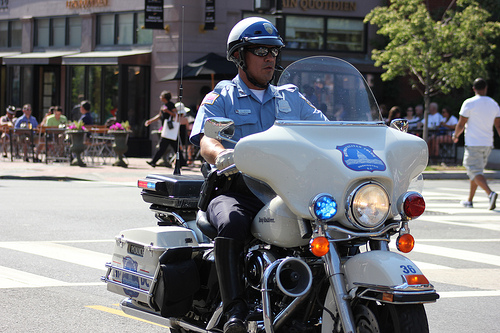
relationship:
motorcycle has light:
[92, 46, 432, 330] [347, 181, 393, 228]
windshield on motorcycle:
[275, 55, 381, 129] [92, 46, 432, 330]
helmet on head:
[221, 17, 286, 52] [221, 16, 286, 86]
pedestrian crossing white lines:
[446, 71, 497, 217] [429, 181, 498, 315]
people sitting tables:
[3, 100, 141, 170] [6, 125, 127, 140]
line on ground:
[0, 227, 116, 276] [0, 176, 500, 333]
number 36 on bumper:
[397, 260, 420, 273] [329, 249, 431, 296]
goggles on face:
[248, 44, 280, 56] [248, 44, 277, 81]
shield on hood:
[330, 134, 396, 181] [230, 123, 430, 233]